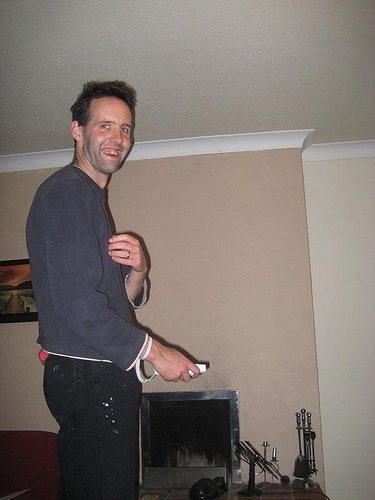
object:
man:
[24, 77, 199, 500]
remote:
[150, 362, 209, 382]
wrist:
[138, 332, 159, 368]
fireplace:
[135, 385, 244, 491]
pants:
[41, 353, 142, 497]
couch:
[0, 430, 63, 500]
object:
[37, 346, 49, 363]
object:
[188, 475, 231, 500]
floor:
[136, 483, 324, 497]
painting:
[1, 258, 39, 321]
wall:
[4, 112, 325, 488]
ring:
[126, 251, 132, 262]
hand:
[141, 334, 203, 383]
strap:
[134, 331, 156, 384]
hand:
[104, 230, 150, 274]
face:
[68, 80, 139, 178]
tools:
[229, 408, 327, 498]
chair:
[2, 426, 351, 498]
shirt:
[25, 162, 150, 368]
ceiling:
[2, 1, 374, 160]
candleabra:
[257, 437, 284, 488]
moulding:
[0, 127, 318, 171]